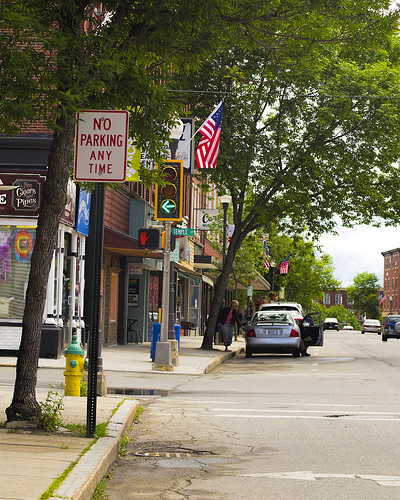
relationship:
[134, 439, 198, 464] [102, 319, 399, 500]
manhole cover in street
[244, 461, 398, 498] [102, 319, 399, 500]
arrow on street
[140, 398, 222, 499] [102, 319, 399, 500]
cracks on street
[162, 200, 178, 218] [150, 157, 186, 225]
arrow on traffic light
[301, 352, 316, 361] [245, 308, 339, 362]
foot coming from car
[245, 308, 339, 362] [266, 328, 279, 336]
car has license plate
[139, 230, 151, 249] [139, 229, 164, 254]
hand says don't walk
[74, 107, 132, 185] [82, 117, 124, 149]
sign says no parking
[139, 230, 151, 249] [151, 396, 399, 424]
hand for crosswalk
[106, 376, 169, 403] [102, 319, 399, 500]
puddle on street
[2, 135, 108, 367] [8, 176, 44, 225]
store has sign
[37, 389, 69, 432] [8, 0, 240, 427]
weeds by tree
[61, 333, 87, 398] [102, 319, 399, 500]
fire hydrant by street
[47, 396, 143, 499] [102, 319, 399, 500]
curb of street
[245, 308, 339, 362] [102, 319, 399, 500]
car on street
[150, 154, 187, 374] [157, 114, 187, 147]
post has light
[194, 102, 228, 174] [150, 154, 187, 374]
flag by post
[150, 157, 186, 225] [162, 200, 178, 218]
traffic light has arrow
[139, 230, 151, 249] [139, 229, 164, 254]
hand signals don't walk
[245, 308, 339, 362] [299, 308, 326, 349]
car has door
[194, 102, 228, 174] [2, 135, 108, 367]
flag by store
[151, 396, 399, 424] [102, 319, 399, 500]
crosswalk on street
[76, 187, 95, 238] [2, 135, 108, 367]
sign on store